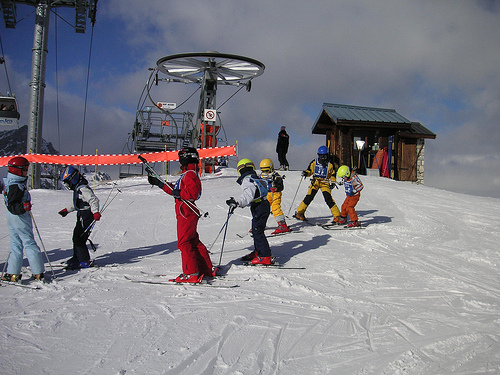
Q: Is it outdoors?
A: Yes, it is outdoors.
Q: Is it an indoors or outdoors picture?
A: It is outdoors.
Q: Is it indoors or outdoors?
A: It is outdoors.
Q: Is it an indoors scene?
A: No, it is outdoors.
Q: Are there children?
A: Yes, there are children.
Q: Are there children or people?
A: Yes, there are children.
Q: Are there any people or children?
A: Yes, there are children.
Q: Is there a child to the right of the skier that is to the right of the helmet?
A: Yes, there are children to the right of the skier.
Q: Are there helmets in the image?
A: Yes, there is a helmet.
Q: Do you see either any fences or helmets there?
A: Yes, there is a helmet.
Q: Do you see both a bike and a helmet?
A: No, there is a helmet but no bikes.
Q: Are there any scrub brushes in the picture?
A: No, there are no scrub brushes.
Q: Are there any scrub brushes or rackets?
A: No, there are no scrub brushes or rackets.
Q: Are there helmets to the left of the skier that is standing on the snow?
A: Yes, there is a helmet to the left of the skier.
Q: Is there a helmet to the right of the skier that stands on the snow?
A: No, the helmet is to the left of the skier.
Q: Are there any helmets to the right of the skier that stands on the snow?
A: No, the helmet is to the left of the skier.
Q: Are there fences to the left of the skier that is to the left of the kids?
A: No, there is a helmet to the left of the skier.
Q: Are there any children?
A: Yes, there is a child.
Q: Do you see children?
A: Yes, there is a child.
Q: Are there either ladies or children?
A: Yes, there is a child.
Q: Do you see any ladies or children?
A: Yes, there is a child.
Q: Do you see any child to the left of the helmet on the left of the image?
A: Yes, there is a child to the left of the helmet.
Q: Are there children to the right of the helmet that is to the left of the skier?
A: No, the child is to the left of the helmet.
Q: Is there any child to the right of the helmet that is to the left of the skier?
A: No, the child is to the left of the helmet.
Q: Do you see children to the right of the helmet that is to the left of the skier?
A: No, the child is to the left of the helmet.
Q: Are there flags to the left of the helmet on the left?
A: No, there is a child to the left of the helmet.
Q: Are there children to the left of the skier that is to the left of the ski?
A: Yes, there is a child to the left of the skier.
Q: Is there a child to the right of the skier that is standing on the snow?
A: No, the child is to the left of the skier.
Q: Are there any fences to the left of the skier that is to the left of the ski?
A: No, there is a child to the left of the skier.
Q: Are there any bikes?
A: No, there are no bikes.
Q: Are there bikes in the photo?
A: No, there are no bikes.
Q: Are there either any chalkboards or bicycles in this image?
A: No, there are no bicycles or chalkboards.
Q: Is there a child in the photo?
A: Yes, there is a child.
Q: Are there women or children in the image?
A: Yes, there is a child.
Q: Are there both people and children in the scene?
A: Yes, there are both a child and a person.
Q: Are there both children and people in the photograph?
A: Yes, there are both a child and a person.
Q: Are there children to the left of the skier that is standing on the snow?
A: Yes, there is a child to the left of the skier.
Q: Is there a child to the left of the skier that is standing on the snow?
A: Yes, there is a child to the left of the skier.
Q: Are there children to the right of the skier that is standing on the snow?
A: No, the child is to the left of the skier.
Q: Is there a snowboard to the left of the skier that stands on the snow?
A: No, there is a child to the left of the skier.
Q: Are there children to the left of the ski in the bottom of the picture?
A: Yes, there is a child to the left of the ski.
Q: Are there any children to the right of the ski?
A: No, the child is to the left of the ski.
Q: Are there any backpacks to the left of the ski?
A: No, there is a child to the left of the ski.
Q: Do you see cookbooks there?
A: No, there are no cookbooks.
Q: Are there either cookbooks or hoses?
A: No, there are no cookbooks or hoses.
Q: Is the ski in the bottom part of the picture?
A: Yes, the ski is in the bottom of the image.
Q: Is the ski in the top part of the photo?
A: No, the ski is in the bottom of the image.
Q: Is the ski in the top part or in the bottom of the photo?
A: The ski is in the bottom of the image.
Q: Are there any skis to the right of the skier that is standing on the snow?
A: Yes, there is a ski to the right of the skier.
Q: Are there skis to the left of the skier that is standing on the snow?
A: No, the ski is to the right of the skier.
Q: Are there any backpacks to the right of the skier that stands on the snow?
A: No, there is a ski to the right of the skier.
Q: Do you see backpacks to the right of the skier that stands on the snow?
A: No, there is a ski to the right of the skier.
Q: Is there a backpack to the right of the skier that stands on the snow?
A: No, there is a ski to the right of the skier.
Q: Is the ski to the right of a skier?
A: Yes, the ski is to the right of a skier.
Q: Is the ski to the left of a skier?
A: No, the ski is to the right of a skier.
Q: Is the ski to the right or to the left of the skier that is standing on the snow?
A: The ski is to the right of the skier.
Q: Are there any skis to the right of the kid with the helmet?
A: Yes, there is a ski to the right of the child.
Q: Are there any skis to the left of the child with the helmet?
A: No, the ski is to the right of the child.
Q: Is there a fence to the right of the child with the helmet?
A: No, there is a ski to the right of the child.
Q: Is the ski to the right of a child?
A: Yes, the ski is to the right of a child.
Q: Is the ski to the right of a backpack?
A: No, the ski is to the right of a child.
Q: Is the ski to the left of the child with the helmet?
A: No, the ski is to the right of the kid.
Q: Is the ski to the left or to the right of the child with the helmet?
A: The ski is to the right of the child.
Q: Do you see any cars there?
A: No, there are no cars.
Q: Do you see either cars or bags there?
A: No, there are no cars or bags.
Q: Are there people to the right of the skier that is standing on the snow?
A: Yes, there is a person to the right of the skier.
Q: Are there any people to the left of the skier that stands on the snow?
A: No, the person is to the right of the skier.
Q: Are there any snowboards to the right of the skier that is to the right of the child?
A: No, there is a person to the right of the skier.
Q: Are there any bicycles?
A: No, there are no bicycles.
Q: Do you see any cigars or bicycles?
A: No, there are no bicycles or cigars.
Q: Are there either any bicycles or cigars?
A: No, there are no bicycles or cigars.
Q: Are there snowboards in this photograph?
A: No, there are no snowboards.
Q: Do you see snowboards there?
A: No, there are no snowboards.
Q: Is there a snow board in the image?
A: No, there are no snowboards.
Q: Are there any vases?
A: No, there are no vases.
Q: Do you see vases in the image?
A: No, there are no vases.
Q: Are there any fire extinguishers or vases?
A: No, there are no vases or fire extinguishers.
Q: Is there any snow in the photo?
A: Yes, there is snow.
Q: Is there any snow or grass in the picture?
A: Yes, there is snow.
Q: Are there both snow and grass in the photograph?
A: No, there is snow but no grass.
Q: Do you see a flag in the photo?
A: No, there are no flags.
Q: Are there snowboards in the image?
A: No, there are no snowboards.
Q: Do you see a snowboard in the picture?
A: No, there are no snowboards.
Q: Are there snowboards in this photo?
A: No, there are no snowboards.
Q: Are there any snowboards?
A: No, there are no snowboards.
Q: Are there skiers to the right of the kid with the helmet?
A: Yes, there is a skier to the right of the child.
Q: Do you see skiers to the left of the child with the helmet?
A: No, the skier is to the right of the child.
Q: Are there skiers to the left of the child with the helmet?
A: No, the skier is to the right of the child.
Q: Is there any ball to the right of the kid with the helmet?
A: No, there is a skier to the right of the kid.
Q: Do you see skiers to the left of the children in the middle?
A: Yes, there is a skier to the left of the kids.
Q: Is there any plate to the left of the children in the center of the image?
A: No, there is a skier to the left of the children.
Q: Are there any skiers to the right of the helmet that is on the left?
A: Yes, there is a skier to the right of the helmet.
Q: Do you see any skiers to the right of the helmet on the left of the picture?
A: Yes, there is a skier to the right of the helmet.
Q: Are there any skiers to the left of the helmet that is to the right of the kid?
A: No, the skier is to the right of the helmet.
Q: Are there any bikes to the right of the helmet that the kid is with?
A: No, there is a skier to the right of the helmet.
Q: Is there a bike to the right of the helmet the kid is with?
A: No, there is a skier to the right of the helmet.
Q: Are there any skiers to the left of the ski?
A: Yes, there is a skier to the left of the ski.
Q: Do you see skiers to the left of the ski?
A: Yes, there is a skier to the left of the ski.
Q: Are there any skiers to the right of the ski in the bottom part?
A: No, the skier is to the left of the ski.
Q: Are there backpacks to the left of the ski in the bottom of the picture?
A: No, there is a skier to the left of the ski.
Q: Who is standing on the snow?
A: The skier is standing on the snow.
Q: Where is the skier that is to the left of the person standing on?
A: The skier is standing on the snow.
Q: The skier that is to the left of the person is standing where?
A: The skier is standing on the snow.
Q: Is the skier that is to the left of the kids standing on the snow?
A: Yes, the skier is standing on the snow.